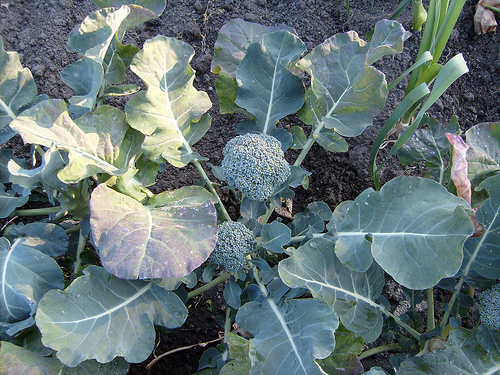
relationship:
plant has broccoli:
[4, 1, 498, 373] [220, 130, 291, 201]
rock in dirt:
[473, 2, 499, 35] [2, 0, 499, 373]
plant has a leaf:
[4, 1, 498, 373] [299, 20, 410, 136]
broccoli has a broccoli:
[220, 130, 291, 201] [220, 130, 291, 201]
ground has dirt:
[2, 2, 496, 374] [2, 0, 499, 373]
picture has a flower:
[2, 2, 499, 373] [441, 133, 481, 232]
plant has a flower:
[4, 1, 498, 373] [441, 133, 481, 232]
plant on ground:
[4, 1, 498, 373] [2, 2, 496, 374]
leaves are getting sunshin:
[62, 4, 215, 166] [2, 2, 220, 288]